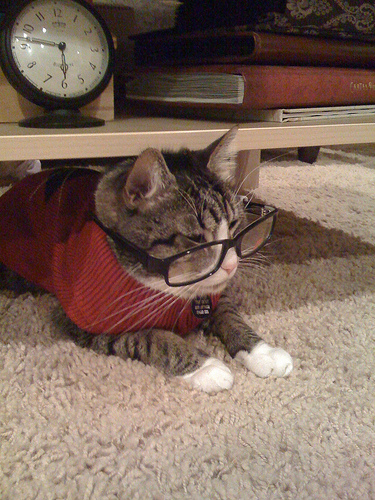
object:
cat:
[0, 126, 292, 392]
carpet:
[1, 181, 361, 493]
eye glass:
[88, 201, 278, 286]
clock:
[1, 2, 116, 128]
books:
[126, 66, 375, 110]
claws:
[183, 356, 235, 392]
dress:
[0, 166, 221, 337]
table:
[0, 119, 374, 187]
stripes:
[174, 157, 231, 223]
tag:
[193, 295, 214, 319]